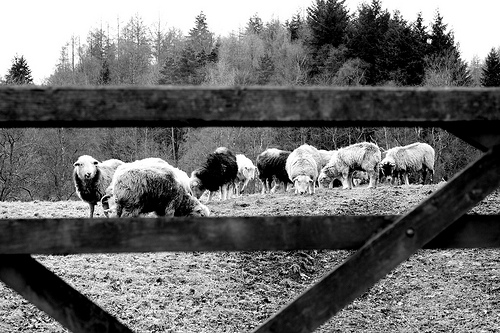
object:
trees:
[1, 0, 498, 201]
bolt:
[402, 223, 418, 241]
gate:
[319, 85, 489, 329]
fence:
[3, 71, 499, 331]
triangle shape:
[48, 250, 324, 331]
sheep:
[112, 158, 202, 219]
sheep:
[67, 147, 119, 213]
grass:
[198, 273, 239, 324]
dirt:
[120, 272, 153, 280]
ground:
[106, 261, 241, 309]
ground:
[289, 185, 414, 209]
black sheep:
[189, 140, 239, 197]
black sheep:
[254, 144, 293, 192]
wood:
[7, 76, 497, 304]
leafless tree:
[2, 127, 33, 201]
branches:
[2, 129, 68, 207]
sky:
[0, 2, 497, 86]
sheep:
[382, 142, 435, 182]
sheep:
[317, 139, 380, 190]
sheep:
[285, 143, 320, 193]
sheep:
[231, 152, 258, 193]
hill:
[9, 19, 479, 202]